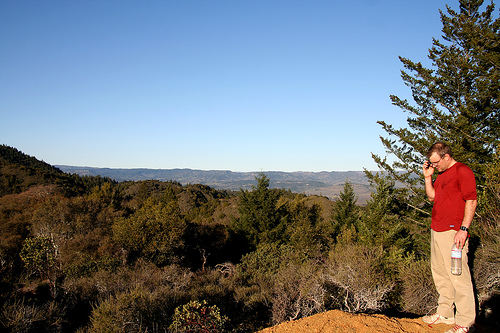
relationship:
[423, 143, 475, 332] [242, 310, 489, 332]
man standing atop hill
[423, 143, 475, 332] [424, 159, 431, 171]
man holding cellphone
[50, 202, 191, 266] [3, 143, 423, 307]
trees below on hill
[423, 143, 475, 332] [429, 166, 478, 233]
man wearing t-shirt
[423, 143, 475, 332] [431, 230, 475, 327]
man wearing pants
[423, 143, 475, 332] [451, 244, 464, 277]
man holding water bottle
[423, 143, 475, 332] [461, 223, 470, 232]
man wearing watch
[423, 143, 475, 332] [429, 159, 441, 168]
man wearing glasses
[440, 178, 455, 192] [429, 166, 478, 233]
logo on t-shirt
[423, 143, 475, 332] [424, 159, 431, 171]
man talking on cellphone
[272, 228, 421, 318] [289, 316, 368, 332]
bushes are near soil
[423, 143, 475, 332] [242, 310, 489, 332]
man on top of hill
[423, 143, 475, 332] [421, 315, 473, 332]
man wearing shoes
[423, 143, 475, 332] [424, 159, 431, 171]
man using cellphone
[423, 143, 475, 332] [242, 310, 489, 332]
man standing on hill